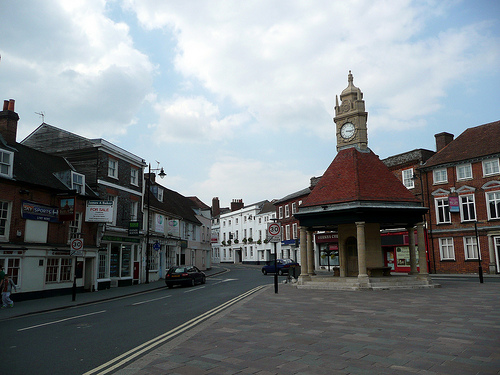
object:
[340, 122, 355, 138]
clock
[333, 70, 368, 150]
tower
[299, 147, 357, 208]
roof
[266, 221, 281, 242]
sign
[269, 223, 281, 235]
circle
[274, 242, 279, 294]
pole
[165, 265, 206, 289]
car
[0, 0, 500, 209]
sky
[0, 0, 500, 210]
clouds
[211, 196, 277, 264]
building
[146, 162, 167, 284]
light pole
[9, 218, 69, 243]
board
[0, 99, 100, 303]
building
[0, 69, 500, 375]
city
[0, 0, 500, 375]
photo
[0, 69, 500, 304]
buildings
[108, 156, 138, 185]
windows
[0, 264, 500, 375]
street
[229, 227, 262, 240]
windows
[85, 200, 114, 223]
sign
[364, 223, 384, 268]
siding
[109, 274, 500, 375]
square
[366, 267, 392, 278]
bench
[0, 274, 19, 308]
man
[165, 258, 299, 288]
cars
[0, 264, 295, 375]
road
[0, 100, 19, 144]
chimney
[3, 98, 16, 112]
pipes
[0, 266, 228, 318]
sidewalk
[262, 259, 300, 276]
car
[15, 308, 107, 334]
line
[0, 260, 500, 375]
ground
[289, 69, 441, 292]
building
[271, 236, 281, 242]
letters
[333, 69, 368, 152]
gazebo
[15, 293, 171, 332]
lines